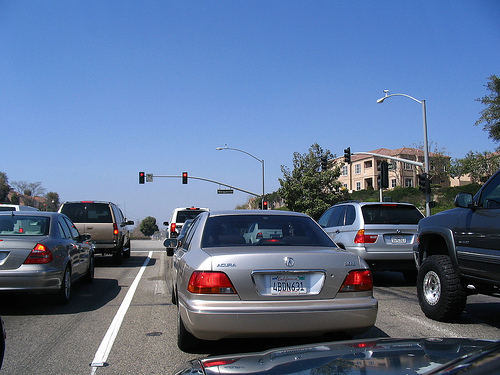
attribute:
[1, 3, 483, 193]
sky — clear, blue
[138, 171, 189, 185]
traffic lights — black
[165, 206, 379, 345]
acura — gold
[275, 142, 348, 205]
tree — tall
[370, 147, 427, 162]
roof — shingled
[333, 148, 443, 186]
house — pink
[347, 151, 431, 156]
roof — brown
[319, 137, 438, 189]
building — spanish style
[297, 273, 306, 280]
tag — California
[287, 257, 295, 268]
logo — acura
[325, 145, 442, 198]
building — tall